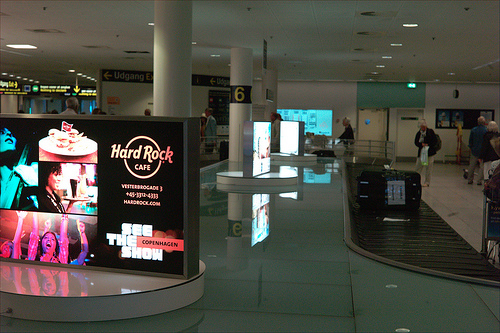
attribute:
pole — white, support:
[228, 47, 253, 164]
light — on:
[400, 20, 417, 30]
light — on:
[388, 39, 404, 49]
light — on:
[380, 54, 394, 62]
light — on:
[377, 64, 387, 69]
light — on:
[373, 71, 381, 76]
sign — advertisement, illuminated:
[243, 119, 272, 176]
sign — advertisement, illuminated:
[278, 119, 303, 156]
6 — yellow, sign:
[234, 84, 248, 102]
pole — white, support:
[151, 1, 194, 124]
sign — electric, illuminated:
[1, 118, 190, 279]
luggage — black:
[356, 170, 424, 216]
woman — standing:
[482, 120, 499, 182]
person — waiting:
[414, 118, 444, 181]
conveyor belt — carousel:
[349, 161, 499, 285]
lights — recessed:
[375, 15, 422, 79]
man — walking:
[467, 117, 487, 186]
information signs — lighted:
[2, 76, 95, 106]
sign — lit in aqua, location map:
[278, 103, 333, 138]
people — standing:
[201, 105, 227, 159]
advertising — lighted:
[256, 120, 276, 173]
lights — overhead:
[6, 33, 96, 84]